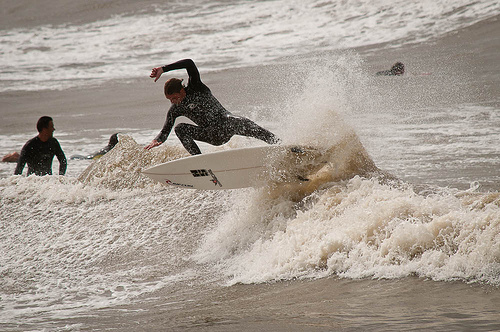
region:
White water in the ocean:
[45, 195, 493, 278]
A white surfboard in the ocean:
[121, 148, 354, 195]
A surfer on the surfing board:
[121, 54, 345, 191]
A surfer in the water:
[16, 108, 71, 208]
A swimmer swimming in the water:
[338, 30, 432, 110]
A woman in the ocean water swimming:
[63, 114, 137, 199]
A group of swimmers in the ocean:
[8, 18, 435, 240]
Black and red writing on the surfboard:
[153, 173, 199, 194]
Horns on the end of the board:
[281, 141, 318, 202]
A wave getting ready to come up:
[216, 4, 498, 154]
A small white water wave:
[30, 193, 465, 295]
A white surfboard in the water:
[138, 137, 339, 194]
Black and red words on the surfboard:
[149, 169, 236, 200]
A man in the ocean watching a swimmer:
[11, 112, 81, 189]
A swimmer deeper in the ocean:
[341, 41, 451, 93]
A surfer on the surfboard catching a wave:
[118, 55, 319, 155]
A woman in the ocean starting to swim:
[66, 115, 141, 200]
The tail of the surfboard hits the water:
[266, 139, 346, 219]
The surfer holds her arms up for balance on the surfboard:
[120, 52, 202, 157]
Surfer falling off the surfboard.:
[164, 66, 259, 165]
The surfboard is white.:
[174, 147, 289, 186]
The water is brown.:
[272, 153, 350, 193]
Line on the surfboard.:
[173, 152, 276, 182]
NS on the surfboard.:
[177, 164, 223, 185]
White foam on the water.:
[67, 27, 141, 56]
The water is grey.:
[0, 0, 95, 26]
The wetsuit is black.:
[16, 141, 60, 178]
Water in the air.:
[286, 71, 337, 113]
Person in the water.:
[377, 56, 415, 81]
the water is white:
[345, 188, 427, 254]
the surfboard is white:
[137, 149, 254, 195]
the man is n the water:
[17, 108, 72, 180]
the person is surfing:
[131, 54, 293, 150]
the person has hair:
[162, 80, 183, 96]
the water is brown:
[217, 288, 348, 325]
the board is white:
[132, 139, 294, 198]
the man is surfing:
[135, 56, 282, 156]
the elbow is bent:
[173, 58, 205, 79]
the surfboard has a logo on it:
[176, 163, 221, 185]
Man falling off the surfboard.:
[131, 48, 326, 181]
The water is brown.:
[260, 135, 381, 185]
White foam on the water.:
[19, 222, 109, 300]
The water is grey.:
[228, 295, 400, 325]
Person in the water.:
[10, 103, 79, 190]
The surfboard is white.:
[153, 138, 316, 193]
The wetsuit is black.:
[18, 135, 71, 177]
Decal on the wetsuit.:
[171, 100, 214, 116]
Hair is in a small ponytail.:
[148, 67, 196, 102]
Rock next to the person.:
[81, 130, 196, 195]